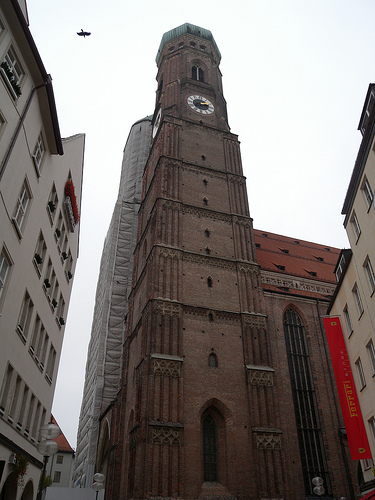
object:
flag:
[313, 304, 374, 468]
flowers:
[59, 174, 89, 228]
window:
[57, 172, 87, 237]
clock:
[185, 89, 217, 121]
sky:
[224, 8, 360, 166]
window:
[272, 293, 322, 500]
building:
[0, 122, 90, 490]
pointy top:
[63, 121, 96, 173]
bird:
[70, 23, 99, 48]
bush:
[6, 450, 39, 482]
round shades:
[304, 469, 333, 499]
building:
[319, 81, 374, 500]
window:
[189, 381, 240, 495]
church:
[108, 12, 300, 498]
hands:
[195, 96, 210, 110]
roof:
[254, 225, 335, 279]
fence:
[148, 34, 228, 67]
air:
[32, 6, 161, 118]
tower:
[134, 12, 261, 297]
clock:
[148, 103, 163, 137]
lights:
[90, 464, 109, 497]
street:
[10, 443, 95, 497]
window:
[194, 150, 211, 165]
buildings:
[121, 23, 283, 498]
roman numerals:
[183, 90, 219, 122]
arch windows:
[204, 345, 221, 370]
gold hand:
[198, 99, 212, 109]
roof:
[148, 17, 228, 78]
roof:
[260, 229, 335, 286]